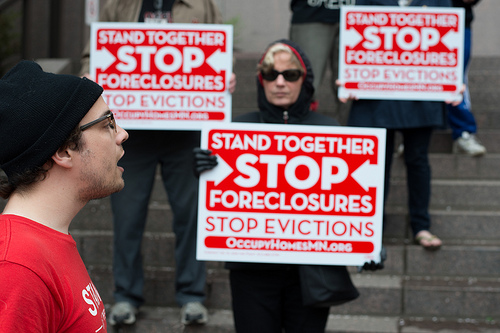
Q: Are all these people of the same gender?
A: No, they are both male and female.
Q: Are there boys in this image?
A: No, there are no boys.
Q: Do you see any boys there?
A: No, there are no boys.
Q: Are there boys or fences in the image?
A: No, there are no boys or fences.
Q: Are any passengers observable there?
A: No, there are no passengers.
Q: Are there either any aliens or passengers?
A: No, there are no passengers or aliens.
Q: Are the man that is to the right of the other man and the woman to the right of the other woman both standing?
A: Yes, both the man and the woman are standing.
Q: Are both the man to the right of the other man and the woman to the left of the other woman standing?
A: Yes, both the man and the woman are standing.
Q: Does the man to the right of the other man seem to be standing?
A: Yes, the man is standing.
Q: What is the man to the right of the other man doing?
A: The man is standing.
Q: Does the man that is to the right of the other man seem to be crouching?
A: No, the man is standing.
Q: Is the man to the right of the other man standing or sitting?
A: The man is standing.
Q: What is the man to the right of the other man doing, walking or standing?
A: The man is standing.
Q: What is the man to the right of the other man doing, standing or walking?
A: The man is standing.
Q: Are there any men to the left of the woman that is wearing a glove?
A: Yes, there is a man to the left of the woman.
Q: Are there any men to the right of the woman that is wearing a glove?
A: No, the man is to the left of the woman.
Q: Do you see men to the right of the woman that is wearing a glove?
A: No, the man is to the left of the woman.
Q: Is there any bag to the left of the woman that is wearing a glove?
A: No, there is a man to the left of the woman.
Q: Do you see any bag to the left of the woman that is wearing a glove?
A: No, there is a man to the left of the woman.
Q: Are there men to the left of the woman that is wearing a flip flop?
A: Yes, there is a man to the left of the woman.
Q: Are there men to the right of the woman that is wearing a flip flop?
A: No, the man is to the left of the woman.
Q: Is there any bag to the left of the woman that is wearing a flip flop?
A: No, there is a man to the left of the woman.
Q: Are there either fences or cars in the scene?
A: No, there are no cars or fences.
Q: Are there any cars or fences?
A: No, there are no cars or fences.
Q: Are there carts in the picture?
A: No, there are no carts.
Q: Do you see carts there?
A: No, there are no carts.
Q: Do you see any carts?
A: No, there are no carts.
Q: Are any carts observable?
A: No, there are no carts.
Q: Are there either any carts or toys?
A: No, there are no carts or toys.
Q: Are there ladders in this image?
A: No, there are no ladders.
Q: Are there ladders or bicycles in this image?
A: No, there are no ladders or bicycles.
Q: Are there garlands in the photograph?
A: No, there are no garlands.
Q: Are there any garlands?
A: No, there are no garlands.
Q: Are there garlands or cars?
A: No, there are no garlands or cars.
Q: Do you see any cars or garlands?
A: No, there are no garlands or cars.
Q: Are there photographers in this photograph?
A: No, there are no photographers.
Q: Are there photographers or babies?
A: No, there are no photographers or babies.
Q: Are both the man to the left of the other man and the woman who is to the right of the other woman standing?
A: Yes, both the man and the woman are standing.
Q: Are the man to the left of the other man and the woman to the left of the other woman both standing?
A: Yes, both the man and the woman are standing.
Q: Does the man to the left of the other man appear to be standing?
A: Yes, the man is standing.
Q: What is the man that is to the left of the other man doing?
A: The man is standing.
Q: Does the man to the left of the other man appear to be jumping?
A: No, the man is standing.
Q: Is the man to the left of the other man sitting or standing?
A: The man is standing.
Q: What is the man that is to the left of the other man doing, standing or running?
A: The man is standing.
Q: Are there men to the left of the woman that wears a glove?
A: Yes, there is a man to the left of the woman.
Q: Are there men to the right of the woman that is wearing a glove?
A: No, the man is to the left of the woman.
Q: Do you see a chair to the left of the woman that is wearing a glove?
A: No, there is a man to the left of the woman.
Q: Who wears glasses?
A: The man wears glasses.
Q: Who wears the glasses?
A: The man wears glasses.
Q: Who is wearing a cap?
A: The man is wearing a cap.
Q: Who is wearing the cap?
A: The man is wearing a cap.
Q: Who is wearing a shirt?
A: The man is wearing a shirt.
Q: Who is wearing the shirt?
A: The man is wearing a shirt.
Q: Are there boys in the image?
A: No, there are no boys.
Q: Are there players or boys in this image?
A: No, there are no boys or players.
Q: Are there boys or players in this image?
A: No, there are no boys or players.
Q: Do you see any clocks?
A: No, there are no clocks.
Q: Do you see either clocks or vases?
A: No, there are no clocks or vases.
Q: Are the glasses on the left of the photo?
A: Yes, the glasses are on the left of the image.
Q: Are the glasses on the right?
A: No, the glasses are on the left of the image.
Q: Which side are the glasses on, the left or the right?
A: The glasses are on the left of the image.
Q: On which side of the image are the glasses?
A: The glasses are on the left of the image.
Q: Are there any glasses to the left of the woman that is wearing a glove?
A: Yes, there are glasses to the left of the woman.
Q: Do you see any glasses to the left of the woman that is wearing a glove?
A: Yes, there are glasses to the left of the woman.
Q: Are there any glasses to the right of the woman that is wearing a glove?
A: No, the glasses are to the left of the woman.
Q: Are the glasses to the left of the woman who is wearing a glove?
A: Yes, the glasses are to the left of the woman.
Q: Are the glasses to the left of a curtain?
A: No, the glasses are to the left of the woman.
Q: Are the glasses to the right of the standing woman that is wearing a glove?
A: No, the glasses are to the left of the woman.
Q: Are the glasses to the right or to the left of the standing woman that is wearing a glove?
A: The glasses are to the left of the woman.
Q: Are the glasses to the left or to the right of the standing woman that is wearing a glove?
A: The glasses are to the left of the woman.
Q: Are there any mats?
A: No, there are no mats.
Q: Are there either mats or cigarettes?
A: No, there are no mats or cigarettes.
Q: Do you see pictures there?
A: No, there are no pictures.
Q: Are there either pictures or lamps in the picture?
A: No, there are no pictures or lamps.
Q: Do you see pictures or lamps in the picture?
A: No, there are no pictures or lamps.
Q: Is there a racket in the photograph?
A: No, there are no rackets.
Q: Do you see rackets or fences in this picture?
A: No, there are no rackets or fences.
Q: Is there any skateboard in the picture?
A: No, there are no skateboards.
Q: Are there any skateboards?
A: No, there are no skateboards.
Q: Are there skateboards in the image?
A: No, there are no skateboards.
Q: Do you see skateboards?
A: No, there are no skateboards.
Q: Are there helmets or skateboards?
A: No, there are no skateboards or helmets.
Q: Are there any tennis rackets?
A: No, there are no tennis rackets.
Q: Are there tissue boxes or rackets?
A: No, there are no rackets or tissue boxes.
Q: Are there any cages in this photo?
A: No, there are no cages.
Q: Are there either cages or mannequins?
A: No, there are no cages or mannequins.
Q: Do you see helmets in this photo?
A: No, there are no helmets.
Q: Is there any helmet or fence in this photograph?
A: No, there are no helmets or fences.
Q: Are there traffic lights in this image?
A: No, there are no traffic lights.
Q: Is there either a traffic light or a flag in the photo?
A: No, there are no traffic lights or flags.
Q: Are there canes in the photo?
A: No, there are no canes.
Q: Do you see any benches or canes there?
A: No, there are no canes or benches.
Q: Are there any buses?
A: No, there are no buses.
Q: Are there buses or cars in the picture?
A: No, there are no buses or cars.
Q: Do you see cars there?
A: No, there are no cars.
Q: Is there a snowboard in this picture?
A: No, there are no snowboards.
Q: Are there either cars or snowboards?
A: No, there are no snowboards or cars.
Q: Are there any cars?
A: No, there are no cars.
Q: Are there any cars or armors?
A: No, there are no cars or armors.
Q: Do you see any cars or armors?
A: No, there are no cars or armors.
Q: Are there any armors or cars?
A: No, there are no cars or armors.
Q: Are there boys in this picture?
A: No, there are no boys.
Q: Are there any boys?
A: No, there are no boys.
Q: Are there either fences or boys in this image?
A: No, there are no boys or fences.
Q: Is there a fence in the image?
A: No, there are no fences.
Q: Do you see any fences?
A: No, there are no fences.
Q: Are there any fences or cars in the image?
A: No, there are no fences or cars.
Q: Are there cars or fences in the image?
A: No, there are no fences or cars.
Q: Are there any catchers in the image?
A: No, there are no catchers.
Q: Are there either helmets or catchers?
A: No, there are no catchers or helmets.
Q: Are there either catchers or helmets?
A: No, there are no catchers or helmets.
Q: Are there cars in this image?
A: No, there are no cars.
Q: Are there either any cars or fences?
A: No, there are no cars or fences.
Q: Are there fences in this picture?
A: No, there are no fences.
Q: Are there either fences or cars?
A: No, there are no fences or cars.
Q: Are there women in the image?
A: Yes, there is a woman.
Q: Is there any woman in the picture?
A: Yes, there is a woman.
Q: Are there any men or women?
A: Yes, there is a woman.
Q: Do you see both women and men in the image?
A: Yes, there are both a woman and a man.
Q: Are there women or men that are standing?
A: Yes, the woman is standing.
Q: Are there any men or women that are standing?
A: Yes, the woman is standing.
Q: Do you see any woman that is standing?
A: Yes, there is a woman that is standing.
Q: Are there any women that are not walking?
A: Yes, there is a woman that is standing.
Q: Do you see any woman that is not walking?
A: Yes, there is a woman that is standing .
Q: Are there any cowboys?
A: No, there are no cowboys.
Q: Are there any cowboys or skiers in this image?
A: No, there are no cowboys or skiers.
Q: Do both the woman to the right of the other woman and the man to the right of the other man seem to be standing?
A: Yes, both the woman and the man are standing.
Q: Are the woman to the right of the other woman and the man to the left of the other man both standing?
A: Yes, both the woman and the man are standing.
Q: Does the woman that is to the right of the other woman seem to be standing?
A: Yes, the woman is standing.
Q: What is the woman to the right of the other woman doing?
A: The woman is standing.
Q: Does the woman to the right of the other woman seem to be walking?
A: No, the woman is standing.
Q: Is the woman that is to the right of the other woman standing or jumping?
A: The woman is standing.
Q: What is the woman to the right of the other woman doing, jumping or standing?
A: The woman is standing.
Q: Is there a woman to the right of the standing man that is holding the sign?
A: Yes, there is a woman to the right of the man.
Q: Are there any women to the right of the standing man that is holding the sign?
A: Yes, there is a woman to the right of the man.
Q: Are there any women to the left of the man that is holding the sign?
A: No, the woman is to the right of the man.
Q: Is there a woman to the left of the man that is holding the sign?
A: No, the woman is to the right of the man.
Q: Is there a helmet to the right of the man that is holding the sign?
A: No, there is a woman to the right of the man.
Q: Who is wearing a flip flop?
A: The woman is wearing a flip flop.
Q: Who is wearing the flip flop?
A: The woman is wearing a flip flop.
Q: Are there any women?
A: Yes, there is a woman.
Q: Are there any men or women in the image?
A: Yes, there is a woman.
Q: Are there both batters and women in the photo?
A: No, there is a woman but no batters.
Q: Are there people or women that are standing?
A: Yes, the woman is standing.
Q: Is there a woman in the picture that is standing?
A: Yes, there is a woman that is standing.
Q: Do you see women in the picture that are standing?
A: Yes, there is a woman that is standing.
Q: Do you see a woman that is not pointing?
A: Yes, there is a woman that is standing .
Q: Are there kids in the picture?
A: No, there are no kids.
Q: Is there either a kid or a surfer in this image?
A: No, there are no children or surfers.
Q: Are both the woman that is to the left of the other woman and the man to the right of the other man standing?
A: Yes, both the woman and the man are standing.